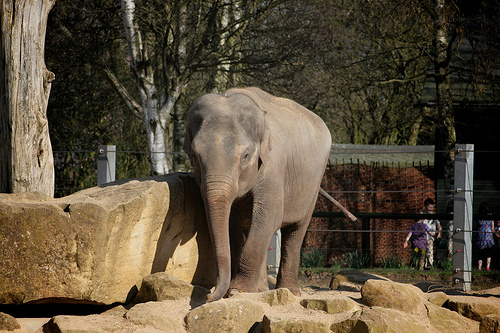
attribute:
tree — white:
[82, 2, 225, 177]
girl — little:
[393, 187, 464, 272]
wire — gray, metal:
[361, 145, 457, 162]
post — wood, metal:
[452, 142, 473, 292]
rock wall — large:
[76, 187, 278, 263]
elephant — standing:
[186, 87, 332, 301]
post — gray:
[96, 140, 119, 186]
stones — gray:
[200, 276, 437, 328]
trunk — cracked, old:
[0, 0, 57, 197]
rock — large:
[7, 165, 216, 297]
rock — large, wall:
[1, 177, 169, 311]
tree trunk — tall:
[4, 4, 52, 210]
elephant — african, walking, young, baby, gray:
[176, 77, 343, 309]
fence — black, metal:
[306, 155, 484, 298]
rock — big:
[356, 270, 420, 302]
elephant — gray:
[139, 64, 352, 259]